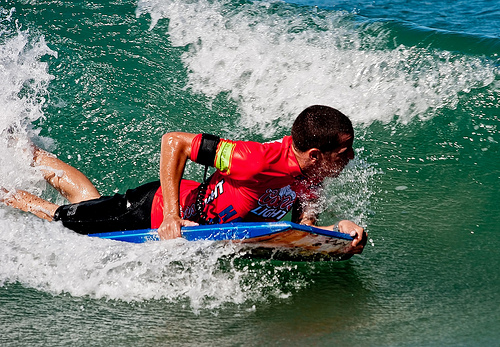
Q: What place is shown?
A: It is an ocean.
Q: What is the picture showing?
A: It is showing an ocean.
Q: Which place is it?
A: It is an ocean.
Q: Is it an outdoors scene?
A: Yes, it is outdoors.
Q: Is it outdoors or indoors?
A: It is outdoors.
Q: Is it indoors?
A: No, it is outdoors.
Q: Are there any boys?
A: No, there are no boys.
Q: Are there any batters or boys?
A: No, there are no boys or batters.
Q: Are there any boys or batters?
A: No, there are no boys or batters.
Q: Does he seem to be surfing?
A: Yes, the man is surfing.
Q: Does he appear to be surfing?
A: Yes, the man is surfing.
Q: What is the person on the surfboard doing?
A: The man is surfing.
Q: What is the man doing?
A: The man is surfing.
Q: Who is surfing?
A: The man is surfing.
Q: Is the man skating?
A: No, the man is surfing.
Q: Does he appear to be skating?
A: No, the man is surfing.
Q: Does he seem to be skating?
A: No, the man is surfing.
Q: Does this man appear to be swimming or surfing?
A: The man is surfing.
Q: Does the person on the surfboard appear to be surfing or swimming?
A: The man is surfing.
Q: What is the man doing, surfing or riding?
A: The man is surfing.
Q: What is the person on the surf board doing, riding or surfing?
A: The man is surfing.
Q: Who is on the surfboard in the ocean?
A: The man is on the surf board.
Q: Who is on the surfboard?
A: The man is on the surf board.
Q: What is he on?
A: The man is on the surf board.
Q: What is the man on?
A: The man is on the surf board.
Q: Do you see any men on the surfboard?
A: Yes, there is a man on the surfboard.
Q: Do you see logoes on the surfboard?
A: No, there is a man on the surfboard.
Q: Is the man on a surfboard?
A: Yes, the man is on a surfboard.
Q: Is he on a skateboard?
A: No, the man is on a surfboard.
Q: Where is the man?
A: The man is in the ocean.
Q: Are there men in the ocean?
A: Yes, there is a man in the ocean.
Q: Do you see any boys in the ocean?
A: No, there is a man in the ocean.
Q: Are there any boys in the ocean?
A: No, there is a man in the ocean.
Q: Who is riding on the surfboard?
A: The man is riding on the surfboard.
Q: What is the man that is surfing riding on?
A: The man is riding on the surfboard.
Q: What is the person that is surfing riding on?
A: The man is riding on the surfboard.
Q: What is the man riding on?
A: The man is riding on the surfboard.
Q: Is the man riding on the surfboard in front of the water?
A: Yes, the man is riding on the surfboard.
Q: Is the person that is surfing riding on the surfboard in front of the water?
A: Yes, the man is riding on the surfboard.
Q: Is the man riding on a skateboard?
A: No, the man is riding on the surfboard.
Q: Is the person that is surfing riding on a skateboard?
A: No, the man is riding on the surfboard.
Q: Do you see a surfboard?
A: Yes, there is a surfboard.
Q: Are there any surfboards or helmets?
A: Yes, there is a surfboard.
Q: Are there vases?
A: No, there are no vases.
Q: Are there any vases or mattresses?
A: No, there are no vases or mattresses.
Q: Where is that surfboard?
A: The surfboard is in the ocean.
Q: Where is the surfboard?
A: The surfboard is in the ocean.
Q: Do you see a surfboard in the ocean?
A: Yes, there is a surfboard in the ocean.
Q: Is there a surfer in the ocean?
A: No, there is a surfboard in the ocean.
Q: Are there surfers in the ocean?
A: No, there is a surfboard in the ocean.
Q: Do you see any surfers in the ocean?
A: No, there is a surfboard in the ocean.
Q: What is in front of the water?
A: The surfboard is in front of the water.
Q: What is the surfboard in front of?
A: The surfboard is in front of the water.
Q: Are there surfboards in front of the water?
A: Yes, there is a surfboard in front of the water.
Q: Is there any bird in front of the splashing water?
A: No, there is a surfboard in front of the water.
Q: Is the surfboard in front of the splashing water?
A: Yes, the surfboard is in front of the water.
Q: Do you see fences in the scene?
A: No, there are no fences.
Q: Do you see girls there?
A: No, there are no girls.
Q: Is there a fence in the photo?
A: No, there are no fences.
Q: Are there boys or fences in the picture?
A: No, there are no fences or boys.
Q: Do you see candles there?
A: No, there are no candles.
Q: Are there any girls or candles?
A: No, there are no candles or girls.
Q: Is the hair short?
A: Yes, the hair is short.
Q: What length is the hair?
A: The hair is short.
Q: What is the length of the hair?
A: The hair is short.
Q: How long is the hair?
A: The hair is short.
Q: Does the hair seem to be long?
A: No, the hair is short.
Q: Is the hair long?
A: No, the hair is short.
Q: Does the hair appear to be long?
A: No, the hair is short.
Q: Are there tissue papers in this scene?
A: No, there are no tissue papers.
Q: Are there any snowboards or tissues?
A: No, there are no tissues or snowboards.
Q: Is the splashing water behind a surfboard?
A: Yes, the water is behind a surfboard.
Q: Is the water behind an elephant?
A: No, the water is behind a surfboard.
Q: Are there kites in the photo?
A: No, there are no kites.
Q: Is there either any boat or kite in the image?
A: No, there are no kites or boats.